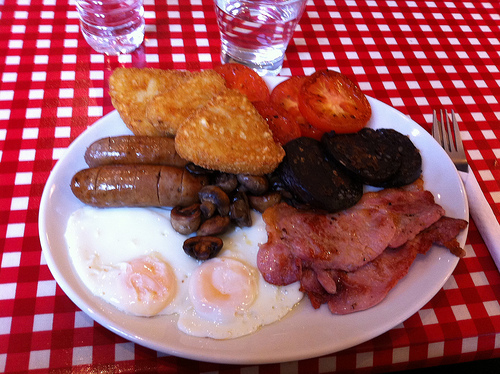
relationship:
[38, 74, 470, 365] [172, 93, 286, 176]
plate full of breakfast food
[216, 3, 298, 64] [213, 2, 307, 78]
water in a glass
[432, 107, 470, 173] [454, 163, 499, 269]
silverware wrapped in a napkin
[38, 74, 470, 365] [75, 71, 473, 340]
plate has breakfast food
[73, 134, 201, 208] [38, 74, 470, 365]
two sausage links are on plate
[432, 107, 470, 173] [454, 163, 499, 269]
fork wrapped in napkin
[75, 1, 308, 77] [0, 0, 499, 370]
two glasses are sitting on table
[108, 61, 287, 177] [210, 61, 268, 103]
two hashbrowns are on top of tomato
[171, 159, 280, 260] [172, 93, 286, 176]
mushrooms are by breakfast food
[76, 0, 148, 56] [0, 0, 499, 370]
water bottle on table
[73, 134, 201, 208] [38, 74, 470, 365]
sausages are on plate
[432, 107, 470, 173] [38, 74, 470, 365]
fork next to plate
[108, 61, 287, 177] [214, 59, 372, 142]
hash browns are next to tomatoes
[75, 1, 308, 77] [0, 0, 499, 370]
bottles of water are on table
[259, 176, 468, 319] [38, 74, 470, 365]
two slices of ham are on plate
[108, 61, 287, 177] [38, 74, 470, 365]
hash browns are on plate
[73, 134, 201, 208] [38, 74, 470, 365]
sausage links are on plate